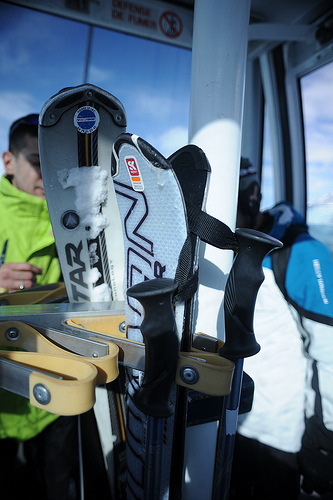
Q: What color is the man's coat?
A: Green.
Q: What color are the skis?
A: Black and white.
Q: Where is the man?
A: Behind the skis.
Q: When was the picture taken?
A: Daytime.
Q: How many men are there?
A: One.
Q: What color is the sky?
A: Blue.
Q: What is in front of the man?
A: The skis.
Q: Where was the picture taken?
A: At a ski resort.